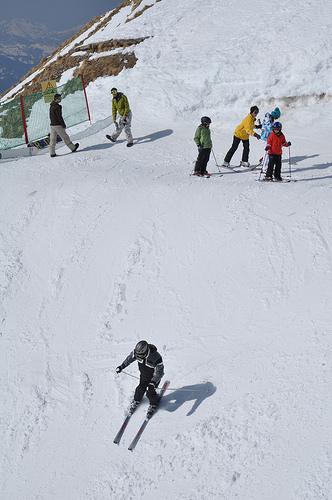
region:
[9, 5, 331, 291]
a mountainside covered in snow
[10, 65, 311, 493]
a ski recreation area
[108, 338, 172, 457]
a person in black is skiing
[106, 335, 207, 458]
the skier is going downhill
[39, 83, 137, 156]
two men are walking along the edge of the ski run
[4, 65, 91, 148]
a fence is behind the men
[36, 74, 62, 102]
a yellow warning sign is on the fence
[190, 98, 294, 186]
a group of children on skis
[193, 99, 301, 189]
four children on skis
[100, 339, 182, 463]
the person skiing is wearing black and grey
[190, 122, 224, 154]
A child wearing a green coat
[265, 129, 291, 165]
A child wearing a red coat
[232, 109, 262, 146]
A person wearing a Yellow coat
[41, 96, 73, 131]
A child wearing a dark coat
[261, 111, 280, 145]
A child wearing a blue and white coat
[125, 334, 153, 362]
A person wearing a ski helmet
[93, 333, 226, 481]
A person skiing down hill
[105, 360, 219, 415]
A person with ski poles in their hands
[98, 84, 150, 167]
A person walking in the snow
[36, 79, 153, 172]
Two men walking in the snow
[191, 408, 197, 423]
part of a shade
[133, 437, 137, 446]
part of a slide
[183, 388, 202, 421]
part of a shade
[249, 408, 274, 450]
part of a grpound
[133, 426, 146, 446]
part of a slide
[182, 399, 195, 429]
part of a shade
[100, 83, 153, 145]
this is a man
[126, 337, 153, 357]
this is the helmet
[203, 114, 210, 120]
the helmet is black in color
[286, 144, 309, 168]
this is a stick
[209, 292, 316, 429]
this is the snow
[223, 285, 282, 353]
the snow is white in color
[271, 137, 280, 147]
this is a jacket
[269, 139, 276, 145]
the jacket is red in color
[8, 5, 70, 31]
this is the sky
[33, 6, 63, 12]
the sky is blue in color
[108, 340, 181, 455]
A person skiing down a hill.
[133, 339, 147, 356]
A grey helmet.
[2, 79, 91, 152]
A green netted fence.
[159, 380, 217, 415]
The shadow of a skier.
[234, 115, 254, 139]
A yellow winter coat.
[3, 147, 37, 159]
A white snowboard.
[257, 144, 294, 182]
Ski poles.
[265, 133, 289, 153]
An orange ski coat.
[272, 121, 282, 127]
A blue helmet.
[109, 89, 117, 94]
A pair of goggles.